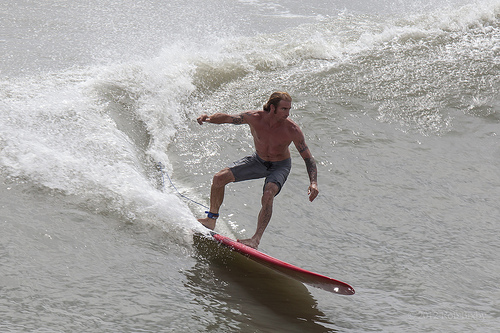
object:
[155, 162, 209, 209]
blue cord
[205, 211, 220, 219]
band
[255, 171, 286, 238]
man's leg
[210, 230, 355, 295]
board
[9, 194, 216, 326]
ripples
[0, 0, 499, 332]
blue water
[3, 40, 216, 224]
white/green waves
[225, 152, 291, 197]
shorts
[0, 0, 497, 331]
waves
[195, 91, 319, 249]
man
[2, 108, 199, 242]
water splashing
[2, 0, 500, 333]
ocean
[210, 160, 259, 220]
leg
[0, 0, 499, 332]
water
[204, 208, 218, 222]
ankle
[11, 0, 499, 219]
ocean waves